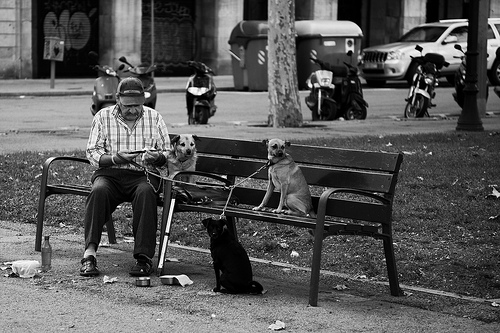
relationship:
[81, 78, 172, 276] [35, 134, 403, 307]
man sitting on a bench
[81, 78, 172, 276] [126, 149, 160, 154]
man looking at object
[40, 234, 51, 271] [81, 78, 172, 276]
bottle next to man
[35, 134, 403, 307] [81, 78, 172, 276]
grass behind man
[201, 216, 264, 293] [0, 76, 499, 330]
dog on ground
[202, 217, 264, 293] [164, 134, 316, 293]
dog are leashed together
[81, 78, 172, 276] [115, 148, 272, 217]
man holding leash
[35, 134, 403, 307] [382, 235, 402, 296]
bench has a leg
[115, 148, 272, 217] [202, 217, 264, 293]
leash on dog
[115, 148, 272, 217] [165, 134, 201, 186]
leash on dog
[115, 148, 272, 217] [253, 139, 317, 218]
leash on dog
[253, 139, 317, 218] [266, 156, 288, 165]
dog wearing a collar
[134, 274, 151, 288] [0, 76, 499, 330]
bowl on ground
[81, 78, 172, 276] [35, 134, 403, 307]
man sitting on bench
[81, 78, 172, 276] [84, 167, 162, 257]
man wearing pants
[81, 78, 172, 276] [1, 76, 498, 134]
man sitting near a road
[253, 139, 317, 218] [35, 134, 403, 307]
dog sitting on bench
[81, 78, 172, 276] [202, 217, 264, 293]
man sitting with h dog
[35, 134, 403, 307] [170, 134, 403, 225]
bench has a back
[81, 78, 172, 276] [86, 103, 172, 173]
man wearing a shirt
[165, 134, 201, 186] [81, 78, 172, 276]
dog next to man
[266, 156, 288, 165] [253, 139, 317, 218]
collar on dog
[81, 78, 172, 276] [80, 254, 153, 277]
man wearing shoes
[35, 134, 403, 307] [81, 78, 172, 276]
bench under man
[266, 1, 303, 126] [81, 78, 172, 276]
tree behind man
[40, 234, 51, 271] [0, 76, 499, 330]
bottle on ground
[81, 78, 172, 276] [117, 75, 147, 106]
man wearing a hat